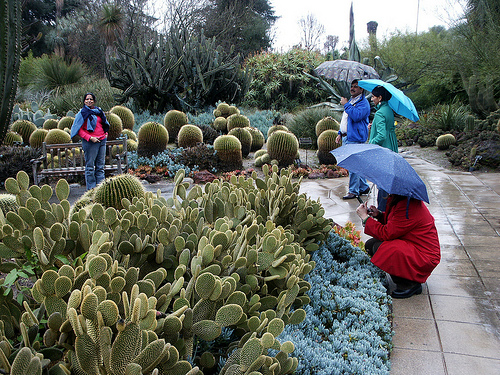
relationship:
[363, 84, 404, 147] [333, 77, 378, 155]
woman near man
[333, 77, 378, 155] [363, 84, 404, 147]
man near woman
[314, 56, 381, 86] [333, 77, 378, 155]
umbrella above man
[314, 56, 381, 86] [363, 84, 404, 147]
umbrella beside woman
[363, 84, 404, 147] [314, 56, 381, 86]
woman beside umbrella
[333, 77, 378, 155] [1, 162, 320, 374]
man near plants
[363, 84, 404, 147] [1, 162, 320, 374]
woman near plants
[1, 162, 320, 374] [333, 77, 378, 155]
plants near man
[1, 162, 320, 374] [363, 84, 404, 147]
plants near woman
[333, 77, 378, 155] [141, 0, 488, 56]
man below sky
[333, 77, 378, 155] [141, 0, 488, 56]
man under sky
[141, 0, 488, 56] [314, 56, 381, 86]
sky above umbrella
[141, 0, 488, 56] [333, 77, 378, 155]
sky above man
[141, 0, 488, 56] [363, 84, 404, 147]
sky above woman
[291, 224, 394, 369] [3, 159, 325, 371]
flowers below cactus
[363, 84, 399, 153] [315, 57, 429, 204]
woman have umbrellas